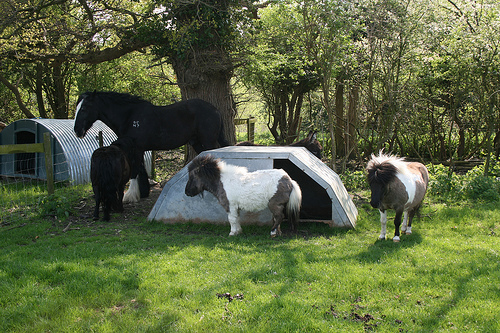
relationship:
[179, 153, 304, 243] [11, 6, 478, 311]
horse in field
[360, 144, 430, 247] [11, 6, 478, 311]
horse in field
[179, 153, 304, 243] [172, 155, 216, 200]
horse has head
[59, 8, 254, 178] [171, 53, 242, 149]
tree has trunk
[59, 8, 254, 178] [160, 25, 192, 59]
tree has leaves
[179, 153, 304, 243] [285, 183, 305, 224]
horse has tail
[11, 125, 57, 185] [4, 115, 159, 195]
front of shed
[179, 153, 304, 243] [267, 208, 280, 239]
horse has leg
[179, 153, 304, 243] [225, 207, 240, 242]
horse has leg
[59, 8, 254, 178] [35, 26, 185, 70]
tree has limb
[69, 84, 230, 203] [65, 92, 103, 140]
horse has face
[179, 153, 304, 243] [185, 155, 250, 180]
horse has mane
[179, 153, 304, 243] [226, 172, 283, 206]
horse has back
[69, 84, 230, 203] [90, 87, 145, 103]
horse has mane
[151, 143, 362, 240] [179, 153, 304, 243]
building behind horse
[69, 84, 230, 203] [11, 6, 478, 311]
horse in field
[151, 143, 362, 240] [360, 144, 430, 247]
building in front of horse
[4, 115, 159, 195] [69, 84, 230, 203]
shed behind horse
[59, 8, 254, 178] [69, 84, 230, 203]
tree behind horse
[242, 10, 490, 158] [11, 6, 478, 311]
trees behind field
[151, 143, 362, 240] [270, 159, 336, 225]
building has door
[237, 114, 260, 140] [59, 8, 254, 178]
fence behind tree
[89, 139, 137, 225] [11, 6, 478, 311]
animal in field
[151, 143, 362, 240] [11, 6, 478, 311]
building in field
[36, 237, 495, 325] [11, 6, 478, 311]
grass in field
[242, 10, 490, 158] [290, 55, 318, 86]
trees have leaves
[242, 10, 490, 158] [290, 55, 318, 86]
trees has leaves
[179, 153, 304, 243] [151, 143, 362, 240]
horse next to building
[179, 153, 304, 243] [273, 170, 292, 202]
horse has backside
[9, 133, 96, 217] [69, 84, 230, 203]
fence next to horse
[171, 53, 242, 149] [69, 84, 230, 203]
trunk next to horse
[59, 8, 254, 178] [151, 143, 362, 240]
tree behind building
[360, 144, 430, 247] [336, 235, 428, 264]
horse has shadow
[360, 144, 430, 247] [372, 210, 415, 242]
horse has legs